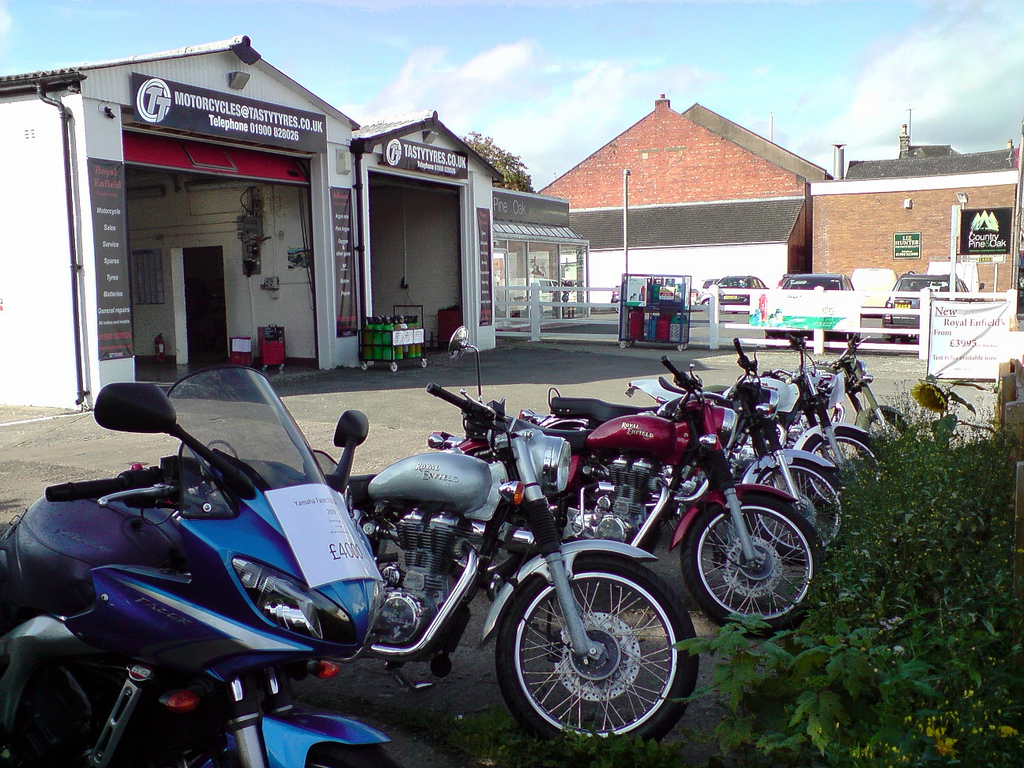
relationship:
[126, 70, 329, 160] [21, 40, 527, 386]
banner on house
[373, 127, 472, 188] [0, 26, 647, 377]
signboard on house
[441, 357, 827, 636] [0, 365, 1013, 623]
bike are on road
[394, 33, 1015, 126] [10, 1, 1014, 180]
clouds are in sky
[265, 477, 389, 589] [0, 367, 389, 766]
paper on motorcycle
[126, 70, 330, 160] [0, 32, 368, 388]
banner on warehouse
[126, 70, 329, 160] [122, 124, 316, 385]
banner over garage openinig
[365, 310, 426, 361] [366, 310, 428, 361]
canisters holding canisters